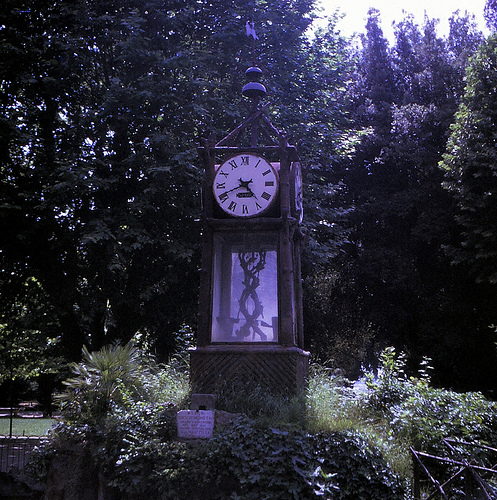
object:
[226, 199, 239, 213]
roman numeral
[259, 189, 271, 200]
roman numeral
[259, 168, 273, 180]
number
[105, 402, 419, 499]
bush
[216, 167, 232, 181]
number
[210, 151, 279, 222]
clock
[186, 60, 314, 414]
tower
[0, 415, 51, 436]
lawn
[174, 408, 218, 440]
sign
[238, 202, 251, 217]
roman numeral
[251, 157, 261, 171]
number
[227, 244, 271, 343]
pattern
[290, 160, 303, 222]
clock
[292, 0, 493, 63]
sunlight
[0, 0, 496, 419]
tree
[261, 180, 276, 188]
number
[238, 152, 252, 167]
number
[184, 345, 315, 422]
base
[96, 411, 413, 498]
ivy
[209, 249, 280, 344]
glass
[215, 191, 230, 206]
number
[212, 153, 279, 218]
face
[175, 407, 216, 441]
engraving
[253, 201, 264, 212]
number